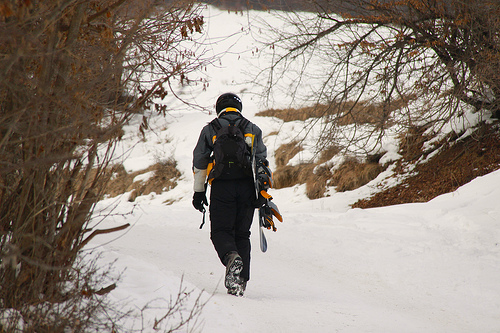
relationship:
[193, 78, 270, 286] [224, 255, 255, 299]
man wearing boots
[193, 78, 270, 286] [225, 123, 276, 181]
man wearing backpack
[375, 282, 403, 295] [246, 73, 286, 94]
snow on ground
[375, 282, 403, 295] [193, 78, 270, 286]
snow surrounding man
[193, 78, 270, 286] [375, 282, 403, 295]
man in snow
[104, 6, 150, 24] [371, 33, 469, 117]
branches of trees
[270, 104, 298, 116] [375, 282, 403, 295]
dirt in snow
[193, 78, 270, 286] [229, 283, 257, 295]
man wearing shoes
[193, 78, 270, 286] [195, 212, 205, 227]
man holding skis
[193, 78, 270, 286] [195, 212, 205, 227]
man carrying skis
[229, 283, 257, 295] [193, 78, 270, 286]
shoes of man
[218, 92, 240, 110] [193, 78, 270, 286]
helmet on man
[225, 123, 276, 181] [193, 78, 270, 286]
backpack on man